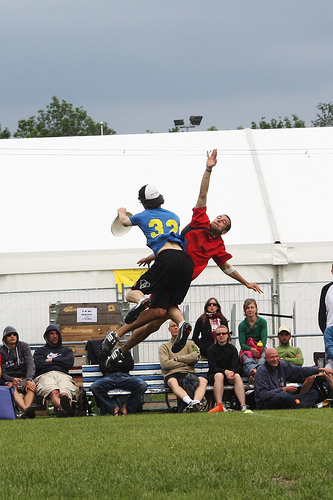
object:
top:
[257, 339, 263, 347]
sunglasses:
[206, 301, 218, 306]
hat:
[138, 184, 163, 209]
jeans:
[91, 372, 148, 412]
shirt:
[33, 343, 74, 374]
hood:
[45, 325, 64, 345]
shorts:
[38, 374, 74, 404]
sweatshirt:
[0, 339, 36, 375]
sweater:
[158, 338, 199, 374]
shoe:
[102, 328, 118, 358]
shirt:
[238, 317, 268, 353]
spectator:
[209, 326, 251, 413]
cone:
[207, 402, 224, 412]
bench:
[80, 358, 262, 417]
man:
[254, 349, 330, 413]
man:
[118, 184, 191, 353]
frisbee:
[111, 210, 133, 238]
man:
[3, 328, 36, 417]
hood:
[3, 327, 20, 349]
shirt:
[131, 209, 185, 249]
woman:
[192, 296, 229, 357]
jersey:
[179, 208, 232, 284]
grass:
[7, 418, 54, 498]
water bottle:
[255, 339, 263, 360]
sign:
[77, 307, 98, 322]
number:
[148, 217, 165, 238]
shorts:
[131, 250, 194, 309]